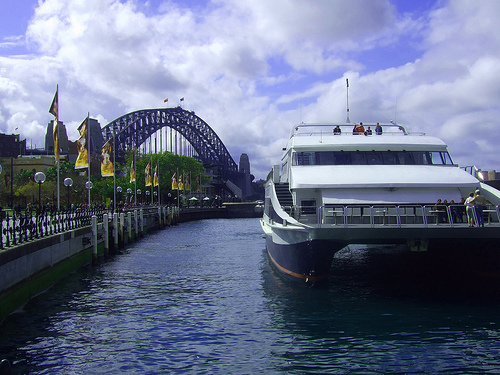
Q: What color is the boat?
A: White.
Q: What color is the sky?
A: Blue.